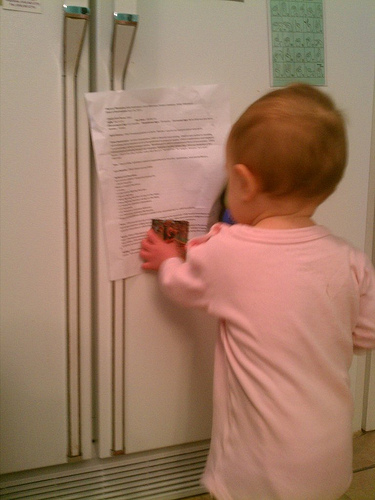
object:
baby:
[140, 82, 374, 500]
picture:
[149, 215, 189, 266]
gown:
[162, 225, 368, 498]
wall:
[49, 0, 63, 149]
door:
[0, 0, 93, 470]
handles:
[64, 4, 91, 458]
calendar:
[265, 0, 327, 90]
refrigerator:
[0, 2, 374, 497]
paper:
[85, 82, 228, 281]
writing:
[0, 0, 42, 17]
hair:
[224, 85, 350, 194]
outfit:
[197, 216, 363, 449]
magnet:
[160, 141, 216, 224]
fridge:
[83, 32, 212, 470]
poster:
[266, 0, 327, 88]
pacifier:
[207, 178, 238, 226]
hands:
[138, 226, 180, 270]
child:
[138, 80, 374, 498]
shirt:
[157, 221, 374, 499]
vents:
[69, 444, 210, 499]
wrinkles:
[218, 306, 308, 437]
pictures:
[139, 218, 194, 264]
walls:
[247, 343, 374, 497]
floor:
[331, 433, 374, 498]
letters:
[104, 105, 210, 257]